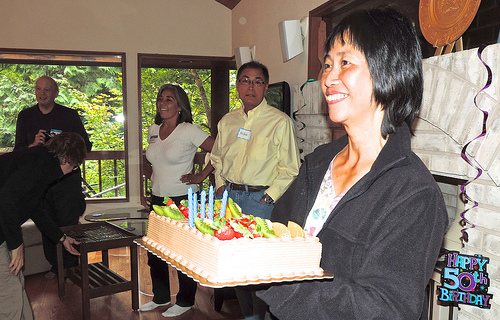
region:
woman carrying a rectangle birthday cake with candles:
[132, 10, 449, 317]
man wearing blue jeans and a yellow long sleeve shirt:
[204, 60, 302, 223]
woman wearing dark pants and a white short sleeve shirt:
[140, 82, 208, 317]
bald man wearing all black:
[13, 73, 93, 285]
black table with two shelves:
[54, 218, 146, 317]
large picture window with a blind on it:
[1, 45, 131, 207]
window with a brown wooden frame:
[134, 51, 222, 207]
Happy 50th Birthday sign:
[432, 246, 496, 317]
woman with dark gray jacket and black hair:
[247, 10, 447, 312]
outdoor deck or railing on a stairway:
[0, 145, 127, 197]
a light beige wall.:
[78, 0, 158, 42]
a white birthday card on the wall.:
[276, 17, 306, 63]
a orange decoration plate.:
[416, 0, 481, 46]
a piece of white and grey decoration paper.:
[426, 98, 461, 155]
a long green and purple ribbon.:
[291, 74, 318, 169]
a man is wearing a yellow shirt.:
[233, 145, 270, 167]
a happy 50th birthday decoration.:
[438, 250, 493, 311]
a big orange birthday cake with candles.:
[132, 183, 336, 289]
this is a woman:
[220, 2, 485, 318]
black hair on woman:
[308, 0, 445, 152]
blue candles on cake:
[168, 174, 255, 234]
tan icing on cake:
[122, 197, 316, 272]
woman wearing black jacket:
[268, 110, 455, 318]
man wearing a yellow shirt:
[211, 102, 288, 199]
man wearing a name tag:
[229, 115, 263, 155]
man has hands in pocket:
[182, 150, 292, 223]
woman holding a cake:
[111, 13, 475, 318]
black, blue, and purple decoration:
[434, 246, 499, 310]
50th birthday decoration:
[429, 245, 499, 313]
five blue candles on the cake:
[176, 173, 238, 232]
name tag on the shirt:
[231, 123, 254, 145]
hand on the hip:
[170, 165, 205, 192]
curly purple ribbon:
[440, 40, 494, 256]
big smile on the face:
[321, 88, 351, 107]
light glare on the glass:
[113, 111, 122, 122]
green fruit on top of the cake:
[149, 199, 181, 220]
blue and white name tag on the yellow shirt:
[233, 125, 253, 142]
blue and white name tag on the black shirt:
[46, 125, 64, 136]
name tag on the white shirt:
[146, 133, 160, 145]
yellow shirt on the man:
[206, 98, 305, 201]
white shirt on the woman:
[142, 120, 213, 198]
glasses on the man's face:
[235, 73, 268, 88]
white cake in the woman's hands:
[129, 183, 336, 291]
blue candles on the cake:
[184, 181, 231, 226]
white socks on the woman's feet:
[136, 297, 195, 319]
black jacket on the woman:
[253, 130, 450, 318]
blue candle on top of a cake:
[183, 184, 194, 227]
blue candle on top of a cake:
[191, 191, 199, 223]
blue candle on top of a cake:
[199, 188, 206, 216]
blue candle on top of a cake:
[207, 181, 215, 218]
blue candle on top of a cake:
[220, 188, 228, 216]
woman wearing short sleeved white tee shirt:
[143, 81, 215, 316]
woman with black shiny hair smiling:
[319, 6, 424, 138]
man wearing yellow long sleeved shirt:
[208, 59, 299, 219]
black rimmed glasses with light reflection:
[233, 74, 269, 90]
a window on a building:
[138, 62, 215, 198]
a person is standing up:
[8, 118, 78, 313]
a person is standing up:
[8, 70, 91, 279]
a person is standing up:
[139, 79, 211, 315]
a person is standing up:
[211, 60, 301, 221]